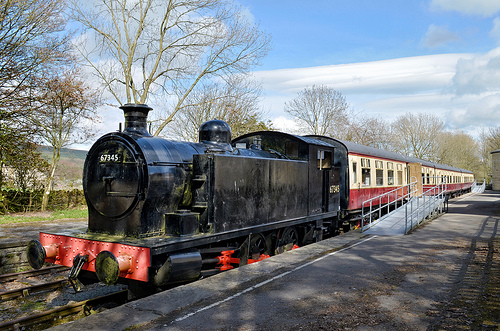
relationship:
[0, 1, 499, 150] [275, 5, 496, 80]
clouds in sky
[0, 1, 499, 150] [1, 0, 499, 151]
clouds in sky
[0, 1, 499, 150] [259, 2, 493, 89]
clouds in sky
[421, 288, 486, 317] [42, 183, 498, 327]
tracks on platform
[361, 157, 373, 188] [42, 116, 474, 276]
window on train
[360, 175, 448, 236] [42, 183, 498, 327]
ramp on platform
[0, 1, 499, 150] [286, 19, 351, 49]
clouds in sky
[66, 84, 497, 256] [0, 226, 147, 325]
train on rail track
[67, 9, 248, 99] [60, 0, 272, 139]
branch of tree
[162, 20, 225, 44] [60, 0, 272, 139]
branch of tree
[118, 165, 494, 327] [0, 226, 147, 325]
concrete near rail track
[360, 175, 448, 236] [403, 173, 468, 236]
ramp with rail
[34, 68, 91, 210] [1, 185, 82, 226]
tree in field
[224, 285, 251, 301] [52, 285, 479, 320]
line on ground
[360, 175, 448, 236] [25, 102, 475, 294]
ramp in front of train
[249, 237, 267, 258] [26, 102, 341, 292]
wheel on locomotive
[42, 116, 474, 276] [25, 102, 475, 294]
train of a train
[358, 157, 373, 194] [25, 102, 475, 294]
window of a train